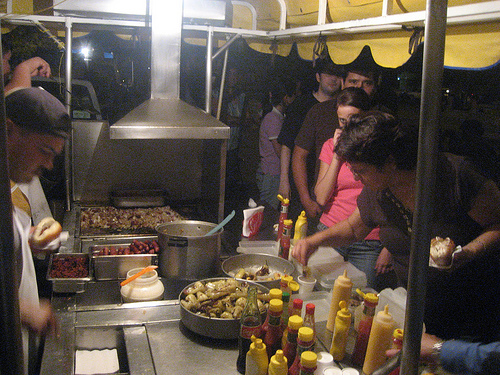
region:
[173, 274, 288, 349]
a pot of food cooking.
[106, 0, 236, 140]
a grill ventilation system.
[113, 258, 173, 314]
a large tub of mayo.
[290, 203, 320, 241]
a bottle of mustard.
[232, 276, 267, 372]
a bottle of coke.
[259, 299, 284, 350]
a bottle of ketchup.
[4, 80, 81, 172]
a man with a black baseball cap.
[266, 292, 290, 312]
a small yellow lid.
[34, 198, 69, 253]
a hot dog bun.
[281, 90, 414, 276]
a woman eating food.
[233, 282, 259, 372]
bottle of Coca Cola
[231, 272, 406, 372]
array of condiments for hot dogs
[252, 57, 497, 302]
people in line for food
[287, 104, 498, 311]
woman adding condiments to her hot dog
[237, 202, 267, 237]
napkins in a red holder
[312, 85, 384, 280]
girl in pink shirt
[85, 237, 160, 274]
cooked hot dogs in metal container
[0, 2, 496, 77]
yellow awning over hot dog stand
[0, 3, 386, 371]
hot dog stand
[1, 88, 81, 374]
man in black baseball cap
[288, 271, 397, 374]
Plastic bottles that contain sauces and condoments.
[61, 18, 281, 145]
Fan hood over a grill.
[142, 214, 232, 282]
Large soup pan with ladel.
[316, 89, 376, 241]
Young girl with a pale red shirt.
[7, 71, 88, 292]
A guy holding a hot dog.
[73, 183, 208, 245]
Food on the grill cookinig.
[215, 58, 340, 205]
Line of people waiting to get their food.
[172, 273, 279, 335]
Veggies in a cooking pot.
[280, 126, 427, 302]
A guy dipping something into a cup.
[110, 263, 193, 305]
A large bottle with a brush laying on top of it.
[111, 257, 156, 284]
large orange spoon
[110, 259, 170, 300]
circular white bowl on stove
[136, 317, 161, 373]
line on silver surface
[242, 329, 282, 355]
yellow lid on condiment bottle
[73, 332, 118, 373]
white paper in silver space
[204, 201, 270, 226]
edge of blue utensil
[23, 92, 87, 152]
black cap on man's head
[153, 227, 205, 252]
black handle on silver pot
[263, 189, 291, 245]
large red ketchup bottle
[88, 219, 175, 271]
silver container with hot dogs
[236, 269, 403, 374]
Many condiment bottles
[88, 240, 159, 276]
A pan of hotdogs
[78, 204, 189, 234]
food cooking on a grill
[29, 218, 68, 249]
A hotdog bun in a paper sleeve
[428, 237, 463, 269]
A hotdog bun in a paper sleeve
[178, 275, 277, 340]
A pan full of potatoes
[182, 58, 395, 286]
People waiting in line for food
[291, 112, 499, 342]
A woman in brown serving herself some food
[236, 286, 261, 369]
A bottle of Coca-Cola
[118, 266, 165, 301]
A jar of mayonnaise